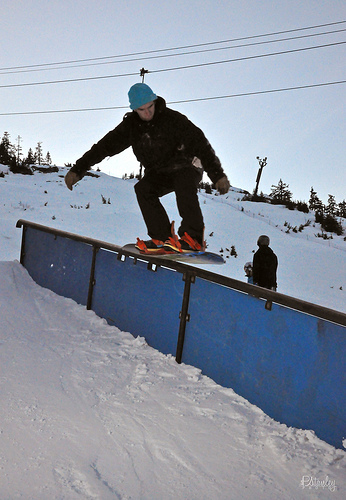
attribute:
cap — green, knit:
[124, 83, 157, 111]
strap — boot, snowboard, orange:
[136, 237, 185, 253]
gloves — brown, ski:
[213, 179, 233, 190]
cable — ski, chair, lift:
[28, 31, 292, 91]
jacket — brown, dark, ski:
[109, 119, 224, 173]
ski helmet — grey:
[258, 233, 270, 248]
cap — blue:
[125, 81, 158, 106]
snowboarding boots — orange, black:
[127, 227, 205, 257]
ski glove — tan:
[213, 175, 234, 197]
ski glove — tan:
[63, 169, 85, 187]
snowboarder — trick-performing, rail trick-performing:
[62, 81, 237, 247]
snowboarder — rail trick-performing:
[59, 81, 240, 260]